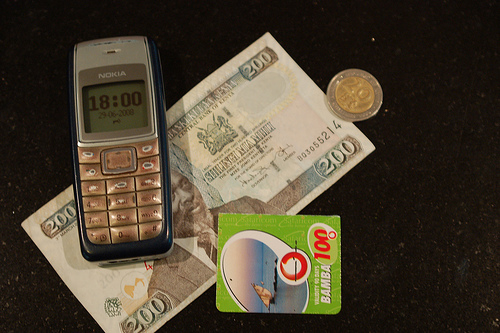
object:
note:
[21, 31, 381, 331]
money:
[20, 31, 383, 331]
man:
[148, 166, 287, 307]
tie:
[195, 235, 219, 269]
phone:
[69, 35, 173, 266]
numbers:
[44, 204, 78, 234]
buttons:
[83, 210, 108, 228]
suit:
[146, 195, 287, 306]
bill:
[19, 30, 379, 332]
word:
[318, 261, 332, 305]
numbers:
[316, 157, 335, 178]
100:
[313, 228, 331, 259]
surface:
[398, 161, 497, 319]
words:
[311, 264, 321, 305]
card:
[215, 212, 343, 312]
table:
[0, 0, 499, 332]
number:
[241, 51, 272, 77]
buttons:
[76, 146, 101, 163]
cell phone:
[66, 34, 173, 264]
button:
[105, 176, 135, 194]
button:
[133, 169, 160, 191]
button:
[135, 186, 160, 208]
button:
[135, 204, 162, 219]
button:
[109, 224, 138, 244]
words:
[167, 82, 236, 141]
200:
[317, 139, 356, 175]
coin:
[325, 67, 383, 121]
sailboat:
[246, 278, 279, 310]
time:
[89, 90, 145, 110]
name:
[97, 70, 129, 79]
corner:
[321, 128, 376, 161]